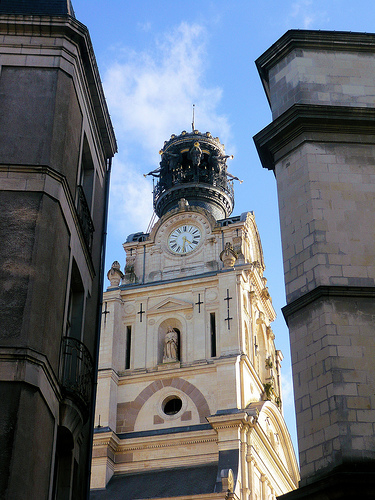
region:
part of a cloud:
[134, 58, 170, 117]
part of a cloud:
[171, 359, 197, 398]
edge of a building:
[222, 420, 253, 476]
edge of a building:
[222, 396, 254, 459]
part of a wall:
[244, 383, 276, 439]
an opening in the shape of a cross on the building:
[100, 301, 108, 321]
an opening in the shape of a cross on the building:
[135, 299, 145, 320]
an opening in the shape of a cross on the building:
[193, 289, 204, 309]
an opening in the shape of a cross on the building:
[221, 287, 233, 307]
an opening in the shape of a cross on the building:
[224, 309, 236, 327]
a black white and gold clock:
[166, 223, 201, 251]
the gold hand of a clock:
[181, 234, 186, 252]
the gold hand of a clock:
[182, 234, 193, 247]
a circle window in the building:
[160, 390, 183, 416]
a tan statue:
[162, 325, 181, 364]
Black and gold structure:
[149, 111, 245, 219]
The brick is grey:
[249, 29, 368, 443]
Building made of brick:
[286, 22, 369, 490]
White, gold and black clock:
[156, 219, 208, 257]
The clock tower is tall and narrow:
[85, 131, 306, 491]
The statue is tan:
[154, 317, 187, 371]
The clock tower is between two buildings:
[6, 47, 366, 463]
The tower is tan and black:
[83, 196, 278, 491]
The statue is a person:
[157, 320, 181, 364]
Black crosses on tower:
[97, 282, 246, 339]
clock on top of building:
[164, 220, 202, 256]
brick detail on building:
[305, 324, 351, 408]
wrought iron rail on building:
[61, 333, 95, 419]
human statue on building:
[160, 321, 179, 364]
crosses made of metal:
[219, 286, 236, 336]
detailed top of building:
[142, 126, 239, 225]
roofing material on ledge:
[139, 473, 181, 490]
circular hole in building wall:
[155, 391, 185, 419]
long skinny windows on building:
[120, 321, 133, 376]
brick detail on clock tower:
[113, 386, 142, 432]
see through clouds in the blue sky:
[111, 15, 211, 88]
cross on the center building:
[193, 292, 203, 315]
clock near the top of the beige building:
[147, 212, 210, 257]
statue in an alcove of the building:
[154, 313, 187, 370]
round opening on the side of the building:
[149, 383, 187, 421]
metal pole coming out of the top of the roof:
[185, 100, 198, 123]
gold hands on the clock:
[179, 233, 194, 252]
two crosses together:
[218, 283, 239, 340]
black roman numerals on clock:
[163, 220, 201, 254]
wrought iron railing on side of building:
[57, 324, 99, 417]